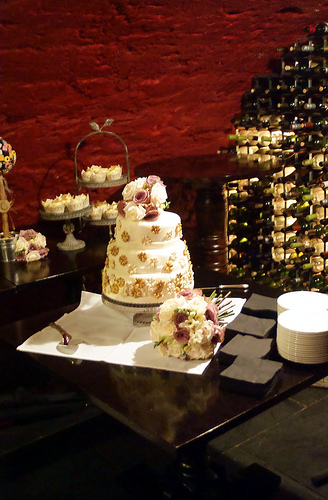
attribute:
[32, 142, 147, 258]
cupcakes — white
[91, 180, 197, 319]
cake — three-tiered, wedding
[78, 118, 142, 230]
metal rack — two tier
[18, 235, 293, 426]
table — black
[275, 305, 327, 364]
plates — white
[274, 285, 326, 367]
plates — stacked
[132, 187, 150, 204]
flower — pink, white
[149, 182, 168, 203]
flower — pink, white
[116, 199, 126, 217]
flower — pink, white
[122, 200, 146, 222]
flower — pink, white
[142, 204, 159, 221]
flower — pink, white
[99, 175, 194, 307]
cake — topper, three tier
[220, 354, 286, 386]
napkin — black, stacked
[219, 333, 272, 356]
napkin — stacked, black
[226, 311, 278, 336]
napkin — stacked, black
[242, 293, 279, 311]
napkin — stacked, black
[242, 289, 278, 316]
napkin — black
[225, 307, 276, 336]
napkin — black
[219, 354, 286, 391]
napkin — black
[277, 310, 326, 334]
plate — white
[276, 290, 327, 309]
plate — white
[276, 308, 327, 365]
dishes — stacked, white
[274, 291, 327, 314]
dishes — white, stacked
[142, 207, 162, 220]
flower — bouquet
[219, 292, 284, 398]
napkins — black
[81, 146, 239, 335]
cake — white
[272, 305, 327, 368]
plates — plastic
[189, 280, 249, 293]
knife — silver, cake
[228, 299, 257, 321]
napkins — black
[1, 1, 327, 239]
wall — red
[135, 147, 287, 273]
table — dark, brown, round, tall, dark brown, wooden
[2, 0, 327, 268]
wall — dark, red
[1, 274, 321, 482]
table — wooden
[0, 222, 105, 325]
table — reflecting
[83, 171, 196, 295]
cake — wedding cake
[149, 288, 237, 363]
flowers — pink, white, bouquet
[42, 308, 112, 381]
server — silver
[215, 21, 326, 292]
bottles — many, Wine 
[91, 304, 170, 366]
cloth — white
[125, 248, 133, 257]
frosting — white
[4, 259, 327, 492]
table — dark, polished, brown, square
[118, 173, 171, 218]
bouquet — small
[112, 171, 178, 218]
flowers — pink, white